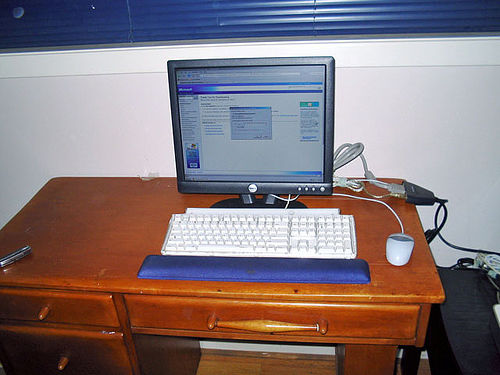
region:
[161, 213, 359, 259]
white computer keyboard on table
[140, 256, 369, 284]
blue padded wrist support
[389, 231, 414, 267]
computer mouse on table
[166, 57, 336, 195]
computer monitor on table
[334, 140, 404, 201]
grey wires on desk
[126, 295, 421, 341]
wood drawer on desk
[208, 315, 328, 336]
handle to desk drawer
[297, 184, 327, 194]
silver buttons on monitor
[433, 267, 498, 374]
black desktop pc tower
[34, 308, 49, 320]
wood knob on door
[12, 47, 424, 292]
a computer sits on a desk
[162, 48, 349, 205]
the monitor is black in color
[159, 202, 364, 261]
the keyboard is cream colored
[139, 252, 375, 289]
a wrist pad sits in front of the keyboard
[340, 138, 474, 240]
a few of the computer hook ups are visible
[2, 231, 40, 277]
another item sits on the desk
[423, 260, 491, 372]
the tower sits on the floor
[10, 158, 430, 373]
the desk is made up of wood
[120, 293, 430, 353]
a drawer is under the top portion of the desk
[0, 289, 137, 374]
two more drawers are on the left hand side of the desk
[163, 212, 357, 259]
white and grey computer keyboard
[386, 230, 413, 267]
white and grey computer mouse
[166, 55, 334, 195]
computer monitor on desk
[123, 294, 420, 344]
wood drawer in desk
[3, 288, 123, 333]
door in computer desk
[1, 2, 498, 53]
blue mini blinds on window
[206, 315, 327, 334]
long handle on drawer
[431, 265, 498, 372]
black plastic computer tower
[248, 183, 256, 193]
silver button on monitor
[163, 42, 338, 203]
black computer monitor on desk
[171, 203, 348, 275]
white keyboard on desk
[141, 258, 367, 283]
blue wrist pad on desk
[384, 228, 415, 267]
gray plastic mouse on desk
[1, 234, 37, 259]
swiss army knife on desk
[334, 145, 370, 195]
gray electric cables on desk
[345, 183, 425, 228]
white mouse wire on desk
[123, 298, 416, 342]
wooden drawer on desk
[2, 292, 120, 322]
wooden drawer on desk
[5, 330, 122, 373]
wooden drawer on desk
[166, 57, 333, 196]
Flat display screen for a computer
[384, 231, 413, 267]
Wired mouse for a computer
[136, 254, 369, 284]
Wrist pad for a computer keyboard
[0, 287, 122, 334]
Top drawer in a desk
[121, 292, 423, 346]
Large drawer in a desk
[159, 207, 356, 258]
Keyboard for desktop computer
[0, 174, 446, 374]
Old wooden writing desk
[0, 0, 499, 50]
Blue vertical blinds in the window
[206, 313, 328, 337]
Large handle to open desk drawer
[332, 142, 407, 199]
Wires for the computer monitor